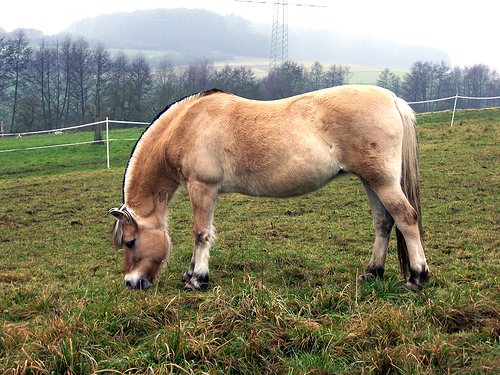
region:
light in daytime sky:
[145, 0, 495, 65]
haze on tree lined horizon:
[71, 12, 453, 71]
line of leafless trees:
[0, 34, 496, 121]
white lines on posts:
[4, 93, 496, 178]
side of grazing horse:
[111, 82, 443, 297]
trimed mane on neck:
[119, 92, 203, 209]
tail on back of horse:
[398, 103, 421, 207]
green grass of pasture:
[8, 105, 495, 361]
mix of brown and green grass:
[20, 293, 472, 373]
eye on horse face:
[120, 233, 142, 254]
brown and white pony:
[95, 82, 457, 297]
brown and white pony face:
[103, 194, 179, 291]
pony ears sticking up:
[106, 200, 141, 225]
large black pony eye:
[120, 235, 142, 251]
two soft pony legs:
[178, 201, 223, 296]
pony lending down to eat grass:
[86, 83, 449, 323]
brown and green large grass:
[38, 295, 301, 362]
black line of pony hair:
[112, 115, 149, 211]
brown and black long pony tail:
[385, 88, 441, 285]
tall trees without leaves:
[7, 30, 125, 142]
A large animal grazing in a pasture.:
[103, 78, 437, 303]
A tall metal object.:
[228, 0, 340, 85]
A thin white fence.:
[3, 84, 498, 176]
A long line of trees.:
[0, 30, 497, 136]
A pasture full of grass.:
[1, 118, 498, 374]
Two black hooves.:
[357, 259, 433, 296]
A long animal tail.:
[383, 94, 430, 284]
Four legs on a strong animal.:
[178, 175, 435, 302]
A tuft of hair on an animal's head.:
[108, 204, 135, 252]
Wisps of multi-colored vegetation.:
[138, 293, 370, 373]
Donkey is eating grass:
[112, 86, 433, 291]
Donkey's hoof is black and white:
[403, 262, 434, 291]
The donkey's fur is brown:
[118, 92, 178, 210]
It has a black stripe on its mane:
[149, 107, 171, 125]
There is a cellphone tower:
[248, 3, 315, 90]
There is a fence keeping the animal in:
[0, 117, 130, 178]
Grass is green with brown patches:
[0, 293, 499, 373]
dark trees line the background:
[0, 56, 167, 111]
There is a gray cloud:
[55, 5, 251, 50]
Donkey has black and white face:
[121, 275, 151, 290]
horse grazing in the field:
[107, 82, 429, 292]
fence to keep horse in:
[2, 114, 150, 176]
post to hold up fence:
[104, 115, 110, 170]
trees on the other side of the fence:
[0, 32, 496, 133]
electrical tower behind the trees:
[241, 0, 335, 75]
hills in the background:
[0, 4, 451, 79]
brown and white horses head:
[108, 200, 173, 292]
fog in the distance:
[2, 0, 499, 57]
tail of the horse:
[396, 94, 424, 274]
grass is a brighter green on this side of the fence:
[1, 125, 145, 183]